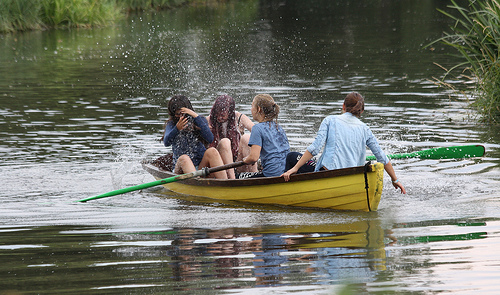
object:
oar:
[365, 144, 486, 162]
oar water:
[356, 128, 476, 168]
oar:
[76, 161, 245, 203]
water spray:
[14, 11, 478, 168]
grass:
[0, 0, 500, 143]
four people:
[163, 92, 406, 195]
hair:
[209, 95, 237, 161]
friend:
[280, 92, 406, 195]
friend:
[236, 94, 291, 180]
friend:
[205, 94, 259, 179]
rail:
[141, 164, 366, 187]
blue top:
[163, 115, 214, 171]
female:
[163, 95, 228, 179]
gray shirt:
[248, 121, 290, 177]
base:
[140, 162, 383, 213]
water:
[17, 55, 410, 295]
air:
[0, 0, 500, 295]